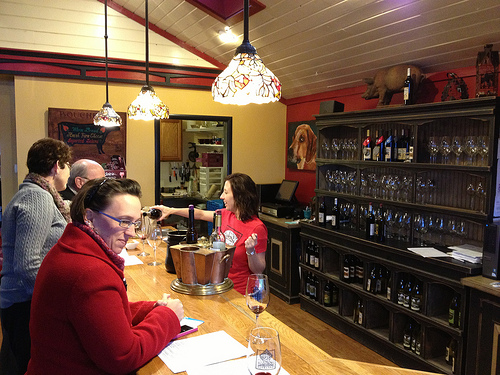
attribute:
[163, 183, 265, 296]
bottles — wine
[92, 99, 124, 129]
light shade — patterened, ceiling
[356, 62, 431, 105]
pig — wooden ,  decorative 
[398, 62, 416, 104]
bottle —  liquor 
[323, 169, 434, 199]
glasses — wine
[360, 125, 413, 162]
bottles — wine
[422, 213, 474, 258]
glass — wine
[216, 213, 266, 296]
t-shirt — red, t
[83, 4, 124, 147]
lamp — decorative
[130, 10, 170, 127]
lamp — decorative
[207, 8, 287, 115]
lamp — decorative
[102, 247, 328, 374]
counter — bar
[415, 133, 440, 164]
glass — wine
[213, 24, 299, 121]
lamp — decorative 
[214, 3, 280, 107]
lamp — very decorative, overhead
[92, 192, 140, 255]
face — woman's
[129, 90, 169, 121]
lamp — decorative 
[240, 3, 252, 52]
pole — black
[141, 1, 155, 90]
pole — black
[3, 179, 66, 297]
sweater — blue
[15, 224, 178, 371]
coat — red